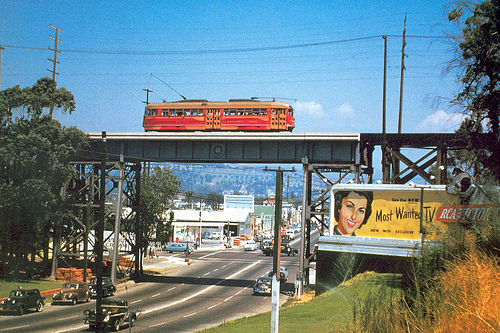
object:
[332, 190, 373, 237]
woman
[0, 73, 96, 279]
trees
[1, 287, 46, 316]
car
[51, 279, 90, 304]
car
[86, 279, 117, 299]
car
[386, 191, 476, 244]
ground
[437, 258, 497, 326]
grass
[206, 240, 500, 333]
field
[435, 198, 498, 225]
advertisement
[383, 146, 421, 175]
ground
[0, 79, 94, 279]
green trees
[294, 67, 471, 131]
clouds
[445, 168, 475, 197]
dog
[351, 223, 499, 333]
foliage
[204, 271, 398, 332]
foreground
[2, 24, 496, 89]
telephone wires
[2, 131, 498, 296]
bridge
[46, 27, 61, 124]
telephone pole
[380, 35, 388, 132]
telephone pole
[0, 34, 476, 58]
telephone lines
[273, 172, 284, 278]
telephone pole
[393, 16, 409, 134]
telephone pole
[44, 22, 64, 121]
telephone pole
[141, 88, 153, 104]
telephone pole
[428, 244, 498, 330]
orange foliage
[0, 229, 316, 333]
on road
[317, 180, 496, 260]
billboard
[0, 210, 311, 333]
road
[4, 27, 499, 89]
wires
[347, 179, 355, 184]
lights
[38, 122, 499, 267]
railway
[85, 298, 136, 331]
car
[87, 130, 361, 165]
beams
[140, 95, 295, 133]
black pipe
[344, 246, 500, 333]
weeds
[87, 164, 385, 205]
city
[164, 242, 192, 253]
car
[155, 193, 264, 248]
shops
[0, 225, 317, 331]
lines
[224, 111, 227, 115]
people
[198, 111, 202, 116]
people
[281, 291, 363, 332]
grass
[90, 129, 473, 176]
overpass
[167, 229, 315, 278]
intersection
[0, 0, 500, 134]
sky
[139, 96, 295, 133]
car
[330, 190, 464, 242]
advertisement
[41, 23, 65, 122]
pole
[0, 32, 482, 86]
lines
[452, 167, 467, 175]
head